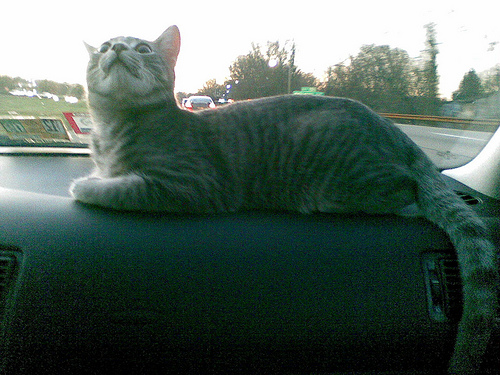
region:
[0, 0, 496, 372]
going for car ride with cat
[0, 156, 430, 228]
front dashboard is black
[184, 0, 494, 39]
Sky in the distance is gray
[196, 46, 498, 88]
Trees are visible from road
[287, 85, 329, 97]
Green road sign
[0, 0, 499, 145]
Glass windshield of vehicle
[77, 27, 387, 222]
Gray stripe cat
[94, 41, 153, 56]
Cat is focused on something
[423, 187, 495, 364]
Cat's tail near the air vent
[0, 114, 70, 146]
a tag for the vehicle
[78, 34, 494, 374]
cat on the top of the car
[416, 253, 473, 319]
the right side car vent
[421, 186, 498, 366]
the cat in the car's tail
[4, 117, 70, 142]
the inspection sticker on the car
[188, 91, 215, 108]
the lights of the car in front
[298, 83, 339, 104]
the green city direction sign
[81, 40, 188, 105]
the face of the cat in the car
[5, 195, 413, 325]
the car's black dashboard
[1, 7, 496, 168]
the car's glass windshield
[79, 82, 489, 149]
the pavement the car is driving on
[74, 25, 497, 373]
cat sitting on car board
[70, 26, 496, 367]
cat is black and gray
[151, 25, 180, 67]
little furry left ear of cat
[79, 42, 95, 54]
little furry right ear of cat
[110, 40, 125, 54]
little pinky nose of cat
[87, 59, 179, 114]
large white whiskers of cat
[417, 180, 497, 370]
large furry tail of cat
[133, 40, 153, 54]
small black and yellow left eye of cat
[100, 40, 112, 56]
small black and yellow left eye of cat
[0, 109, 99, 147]
small decals on windshield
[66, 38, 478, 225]
The cat is sitting.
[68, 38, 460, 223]
The cat is grey.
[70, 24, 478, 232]
The cat is looking up.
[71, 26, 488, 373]
The cat is sitting in a car.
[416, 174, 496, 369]
His tail is over a vent.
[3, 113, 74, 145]
The license plate is in the car.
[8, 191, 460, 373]
The dash board is grey.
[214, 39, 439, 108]
The trees are leafy.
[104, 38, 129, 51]
His nose is black.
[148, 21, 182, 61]
His ear is sticking up.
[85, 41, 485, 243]
the cat is loking up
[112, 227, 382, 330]
the dashboard is plastic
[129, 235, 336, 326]
the dashboard is grey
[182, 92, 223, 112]
the car has lights on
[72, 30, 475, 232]
the cat is inside the car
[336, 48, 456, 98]
trees are in the background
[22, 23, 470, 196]
it is daytime in the photo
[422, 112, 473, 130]
the metal barricade is rusted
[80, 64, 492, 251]
the cat is grey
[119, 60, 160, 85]
the whhiskers are white